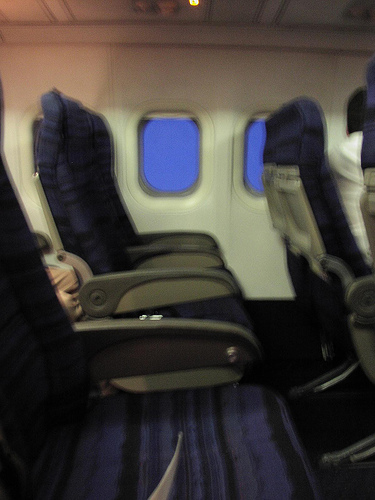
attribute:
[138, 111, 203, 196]
window — blue, small, open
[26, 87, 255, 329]
seat — striped, grey, empty, blue, black, cushioned, upright, vacant, plush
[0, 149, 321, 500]
seat — empty, black, blue, cushioned, upright, vacant, plush, striped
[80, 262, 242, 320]
armrest — down, plastic, grey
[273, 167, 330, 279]
tray table — up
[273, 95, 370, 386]
seat — plush, striped, empty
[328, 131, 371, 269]
shirt — white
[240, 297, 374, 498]
carpet — dark colored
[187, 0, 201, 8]
light — orange, small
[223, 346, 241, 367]
button — silver, small